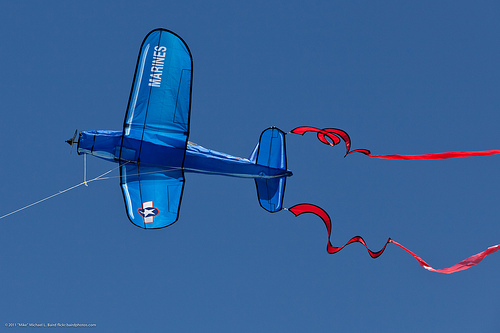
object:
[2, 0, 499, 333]
scene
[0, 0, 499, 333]
day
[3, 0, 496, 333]
no clouds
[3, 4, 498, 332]
is blue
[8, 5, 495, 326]
it is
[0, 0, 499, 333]
sky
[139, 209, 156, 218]
star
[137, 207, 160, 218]
circle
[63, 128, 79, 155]
propeller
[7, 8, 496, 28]
blue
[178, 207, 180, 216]
black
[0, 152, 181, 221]
string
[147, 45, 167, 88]
marines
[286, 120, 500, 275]
long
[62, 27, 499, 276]
airplane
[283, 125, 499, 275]
ribbon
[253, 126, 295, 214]
wing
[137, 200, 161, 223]
logo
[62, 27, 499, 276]
flying